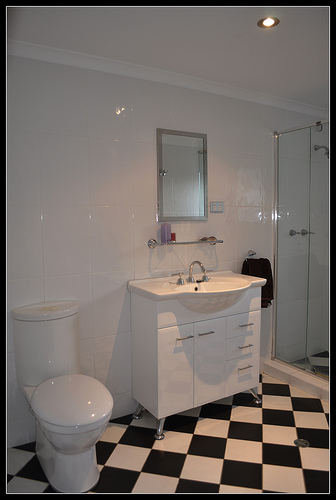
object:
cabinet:
[130, 268, 267, 422]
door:
[161, 332, 190, 414]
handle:
[179, 337, 192, 342]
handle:
[199, 330, 214, 337]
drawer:
[239, 321, 255, 331]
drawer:
[231, 342, 256, 356]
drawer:
[237, 366, 253, 373]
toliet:
[11, 300, 113, 498]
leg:
[251, 391, 261, 403]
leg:
[136, 407, 144, 415]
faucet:
[188, 260, 206, 281]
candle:
[159, 226, 171, 244]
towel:
[254, 262, 270, 274]